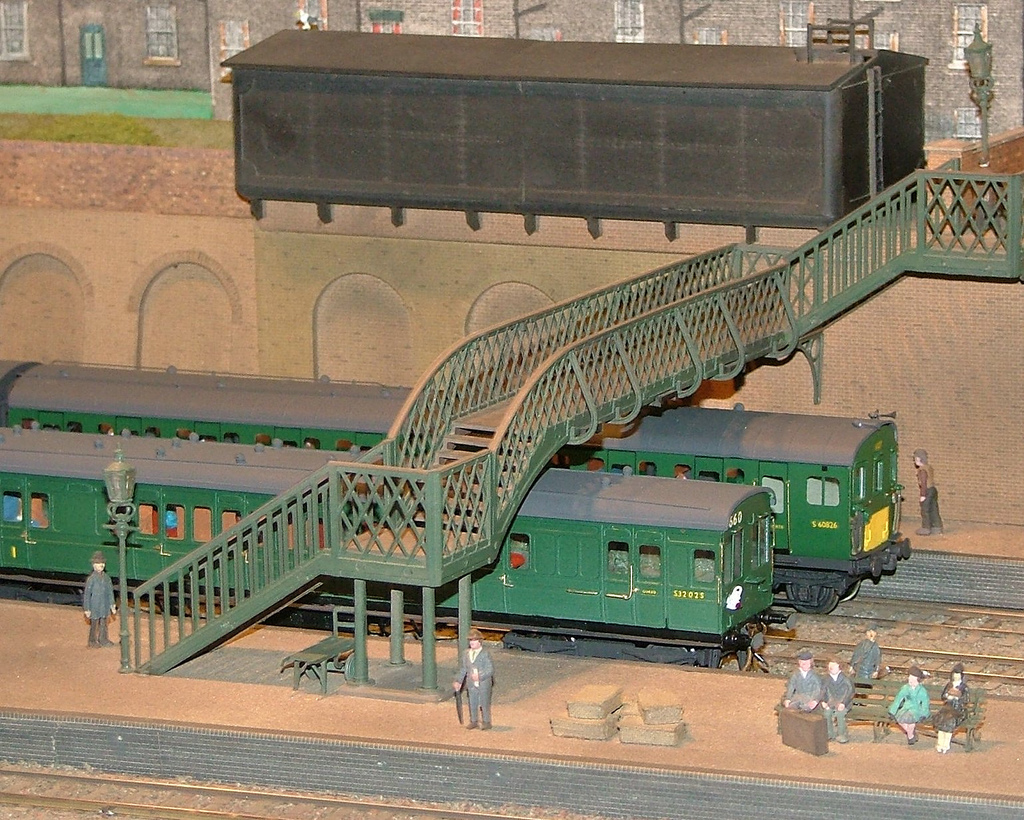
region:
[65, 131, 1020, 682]
the stairs are color green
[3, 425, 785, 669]
train behind the stairs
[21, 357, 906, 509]
train behind the stairs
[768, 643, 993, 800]
people sitting on a bench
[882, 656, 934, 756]
woman sits on a bench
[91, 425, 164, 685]
a street light next to the stairs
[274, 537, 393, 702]
a bench under the stairs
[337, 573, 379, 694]
the pole is color green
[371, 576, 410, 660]
the pole is color green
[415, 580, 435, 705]
the pole is color green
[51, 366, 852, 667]
two green toy trains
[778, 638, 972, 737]
people sitting on bench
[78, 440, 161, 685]
light post near train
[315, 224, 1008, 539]
brown wall next to train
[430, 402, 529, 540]
grey steps on walkway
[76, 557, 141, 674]
man at bottom of walkway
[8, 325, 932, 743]
a set of trains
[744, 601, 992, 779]
a group of people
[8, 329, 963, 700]
the trains are green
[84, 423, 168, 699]
a green light post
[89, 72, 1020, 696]
a set of stairs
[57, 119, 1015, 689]
green rails on the stairs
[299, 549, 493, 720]
posts under the stairs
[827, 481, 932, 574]
yellow trim on train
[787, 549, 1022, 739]
set of train tracks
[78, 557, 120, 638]
the person is standing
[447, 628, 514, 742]
the person is standing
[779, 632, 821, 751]
the person is standing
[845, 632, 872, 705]
the person is standing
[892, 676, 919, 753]
the person is standing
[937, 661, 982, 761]
the person is standing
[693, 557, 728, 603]
window on the train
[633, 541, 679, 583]
window on the train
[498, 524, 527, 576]
window on the train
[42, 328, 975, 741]
a pair of model trains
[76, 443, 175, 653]
a model lamp post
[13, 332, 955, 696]
the trains are green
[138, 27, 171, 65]
glass window on the building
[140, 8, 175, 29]
glass window on the building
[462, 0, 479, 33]
glass window on the building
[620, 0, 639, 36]
glass window on the building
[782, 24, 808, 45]
glass window on the building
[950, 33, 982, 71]
glass window on the building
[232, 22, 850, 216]
large brown wooden structure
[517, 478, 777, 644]
green and gray passenger train car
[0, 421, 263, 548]
green and gray passenger train car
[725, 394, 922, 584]
green and gray passenger train car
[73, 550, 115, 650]
man standing on train platform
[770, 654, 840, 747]
man standing on train platform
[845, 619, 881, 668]
man standing on train platform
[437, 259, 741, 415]
green stairs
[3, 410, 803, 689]
front train is green